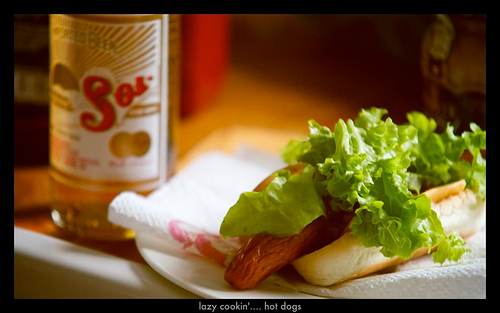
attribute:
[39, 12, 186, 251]
bottle — glass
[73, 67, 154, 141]
letters — red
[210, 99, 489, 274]
lettuce — green, fresh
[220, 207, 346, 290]
hot dog — wrinkled, meat, short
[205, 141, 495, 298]
bun — white, brown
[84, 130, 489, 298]
napkin — round, paper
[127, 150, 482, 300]
plate — white, solid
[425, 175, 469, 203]
cheese — yellow